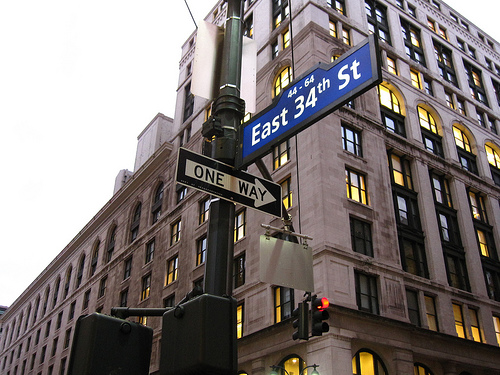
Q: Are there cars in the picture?
A: No, there are no cars.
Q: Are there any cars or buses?
A: No, there are no cars or buses.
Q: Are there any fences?
A: No, there are no fences.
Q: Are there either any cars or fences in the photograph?
A: No, there are no fences or cars.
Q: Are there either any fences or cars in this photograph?
A: No, there are no fences or cars.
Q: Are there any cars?
A: No, there are no cars.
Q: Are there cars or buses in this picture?
A: No, there are no cars or buses.